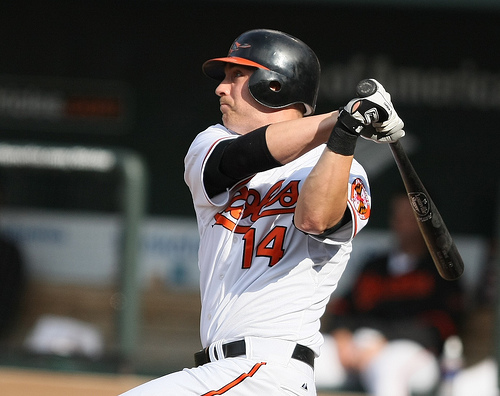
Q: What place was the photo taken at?
A: It was taken at the stadium.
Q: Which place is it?
A: It is a stadium.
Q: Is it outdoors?
A: Yes, it is outdoors.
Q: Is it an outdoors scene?
A: Yes, it is outdoors.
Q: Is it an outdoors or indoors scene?
A: It is outdoors.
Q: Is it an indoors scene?
A: No, it is outdoors.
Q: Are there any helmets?
A: Yes, there is a helmet.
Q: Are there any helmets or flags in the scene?
A: Yes, there is a helmet.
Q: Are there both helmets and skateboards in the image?
A: No, there is a helmet but no skateboards.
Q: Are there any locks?
A: No, there are no locks.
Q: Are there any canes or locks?
A: No, there are no locks or canes.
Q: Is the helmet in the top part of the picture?
A: Yes, the helmet is in the top of the image.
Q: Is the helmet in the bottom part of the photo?
A: No, the helmet is in the top of the image.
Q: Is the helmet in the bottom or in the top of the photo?
A: The helmet is in the top of the image.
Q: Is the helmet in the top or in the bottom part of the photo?
A: The helmet is in the top of the image.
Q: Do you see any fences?
A: No, there are no fences.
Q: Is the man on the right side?
A: Yes, the man is on the right of the image.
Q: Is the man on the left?
A: No, the man is on the right of the image.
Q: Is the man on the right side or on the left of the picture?
A: The man is on the right of the image.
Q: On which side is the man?
A: The man is on the right of the image.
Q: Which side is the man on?
A: The man is on the right of the image.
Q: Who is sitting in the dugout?
A: The man is sitting in the dugout.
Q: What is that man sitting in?
A: The man is sitting in the dugout.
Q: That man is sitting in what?
A: The man is sitting in the dugout.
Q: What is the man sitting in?
A: The man is sitting in the dugout.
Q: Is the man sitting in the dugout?
A: Yes, the man is sitting in the dugout.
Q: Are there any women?
A: No, there are no women.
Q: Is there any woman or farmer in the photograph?
A: No, there are no women or farmers.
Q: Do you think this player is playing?
A: Yes, the player is playing.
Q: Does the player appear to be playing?
A: Yes, the player is playing.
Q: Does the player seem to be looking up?
A: No, the player is playing.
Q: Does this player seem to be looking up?
A: No, the player is playing.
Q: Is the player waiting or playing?
A: The player is playing.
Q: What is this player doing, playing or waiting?
A: The player is playing.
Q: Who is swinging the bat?
A: The player is swinging the bat.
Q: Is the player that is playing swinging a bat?
A: Yes, the player is swinging a bat.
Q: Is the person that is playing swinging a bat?
A: Yes, the player is swinging a bat.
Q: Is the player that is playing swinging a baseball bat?
A: No, the player is swinging a bat.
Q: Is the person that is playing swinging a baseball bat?
A: No, the player is swinging a bat.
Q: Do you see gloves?
A: Yes, there are gloves.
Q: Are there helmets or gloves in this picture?
A: Yes, there are gloves.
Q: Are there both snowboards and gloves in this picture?
A: No, there are gloves but no snowboards.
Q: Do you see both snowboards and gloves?
A: No, there are gloves but no snowboards.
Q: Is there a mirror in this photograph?
A: No, there are no mirrors.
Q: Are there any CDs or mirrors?
A: No, there are no mirrors or cds.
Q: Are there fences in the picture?
A: No, there are no fences.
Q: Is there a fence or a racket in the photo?
A: No, there are no fences or rackets.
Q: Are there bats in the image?
A: Yes, there is a bat.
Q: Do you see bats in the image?
A: Yes, there is a bat.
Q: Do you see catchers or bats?
A: Yes, there is a bat.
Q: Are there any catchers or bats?
A: Yes, there is a bat.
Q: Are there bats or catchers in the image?
A: Yes, there is a bat.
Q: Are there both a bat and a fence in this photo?
A: No, there is a bat but no fences.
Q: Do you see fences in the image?
A: No, there are no fences.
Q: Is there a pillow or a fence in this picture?
A: No, there are no fences or pillows.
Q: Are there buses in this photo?
A: No, there are no buses.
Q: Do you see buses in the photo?
A: No, there are no buses.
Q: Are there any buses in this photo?
A: No, there are no buses.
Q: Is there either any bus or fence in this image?
A: No, there are no buses or fences.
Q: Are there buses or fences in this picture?
A: No, there are no buses or fences.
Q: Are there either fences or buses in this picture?
A: No, there are no buses or fences.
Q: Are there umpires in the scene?
A: No, there are no umpires.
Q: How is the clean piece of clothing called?
A: The clothing item is a uniform.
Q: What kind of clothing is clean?
A: The clothing is a uniform.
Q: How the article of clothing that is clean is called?
A: The clothing item is a uniform.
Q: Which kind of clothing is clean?
A: The clothing is a uniform.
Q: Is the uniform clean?
A: Yes, the uniform is clean.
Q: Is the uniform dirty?
A: No, the uniform is clean.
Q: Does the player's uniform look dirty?
A: No, the uniform is clean.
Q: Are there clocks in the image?
A: No, there are no clocks.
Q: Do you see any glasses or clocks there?
A: No, there are no clocks or glasses.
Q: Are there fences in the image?
A: No, there are no fences.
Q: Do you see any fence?
A: No, there are no fences.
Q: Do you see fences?
A: No, there are no fences.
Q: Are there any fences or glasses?
A: No, there are no fences or glasses.